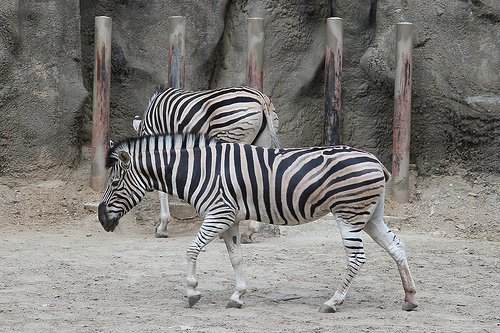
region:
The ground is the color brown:
[27, 241, 157, 321]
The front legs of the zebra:
[176, 209, 253, 311]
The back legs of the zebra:
[318, 217, 421, 316]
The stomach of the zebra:
[241, 143, 326, 225]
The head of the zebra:
[93, 111, 143, 242]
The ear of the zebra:
[115, 142, 135, 172]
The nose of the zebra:
[92, 203, 112, 230]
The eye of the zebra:
[105, 172, 125, 193]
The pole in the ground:
[378, 19, 425, 209]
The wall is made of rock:
[431, 23, 485, 143]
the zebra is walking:
[77, 140, 417, 331]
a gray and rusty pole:
[72, 32, 122, 168]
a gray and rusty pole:
[154, 10, 206, 192]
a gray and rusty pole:
[228, 25, 290, 220]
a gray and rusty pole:
[312, 20, 363, 210]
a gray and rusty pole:
[392, 3, 427, 245]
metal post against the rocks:
[385, 8, 428, 214]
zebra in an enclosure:
[88, 125, 435, 325]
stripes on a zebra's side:
[236, 156, 295, 206]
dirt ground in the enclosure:
[16, 257, 103, 316]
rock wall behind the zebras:
[14, 39, 89, 176]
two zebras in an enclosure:
[102, 80, 409, 330]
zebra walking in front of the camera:
[69, 123, 431, 311]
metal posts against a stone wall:
[240, 6, 427, 96]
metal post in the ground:
[385, 160, 414, 227]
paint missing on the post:
[326, 45, 341, 113]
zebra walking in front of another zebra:
[96, 83, 422, 313]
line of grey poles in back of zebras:
[81, 10, 411, 190]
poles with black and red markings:
[90, 5, 410, 195]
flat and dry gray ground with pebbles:
[15, 221, 496, 326]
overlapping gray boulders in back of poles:
[0, 5, 491, 202]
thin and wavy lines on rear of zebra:
[215, 121, 257, 137]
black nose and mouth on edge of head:
[91, 190, 116, 230]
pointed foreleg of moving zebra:
[180, 165, 235, 310]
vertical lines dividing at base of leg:
[195, 142, 241, 214]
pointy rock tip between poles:
[326, 18, 407, 94]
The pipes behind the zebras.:
[86, 14, 421, 216]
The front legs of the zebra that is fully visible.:
[175, 213, 251, 305]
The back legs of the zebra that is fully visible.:
[327, 207, 423, 312]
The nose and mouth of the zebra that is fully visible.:
[90, 198, 118, 238]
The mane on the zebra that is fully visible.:
[95, 135, 221, 160]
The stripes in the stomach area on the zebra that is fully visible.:
[229, 152, 338, 223]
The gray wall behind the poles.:
[1, 1, 498, 191]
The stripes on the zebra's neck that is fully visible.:
[136, 148, 211, 200]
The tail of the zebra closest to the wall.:
[257, 98, 278, 149]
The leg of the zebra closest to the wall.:
[158, 184, 174, 244]